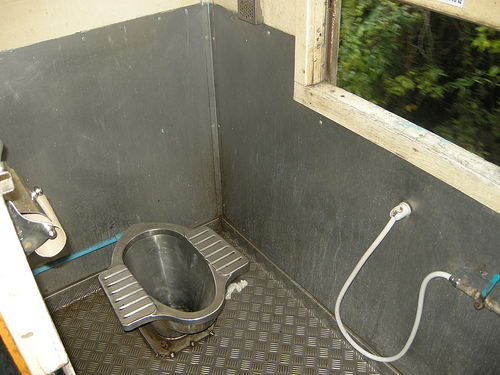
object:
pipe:
[22, 187, 67, 259]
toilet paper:
[23, 195, 67, 257]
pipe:
[32, 231, 125, 279]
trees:
[341, 12, 486, 130]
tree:
[331, 0, 499, 166]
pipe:
[447, 267, 500, 318]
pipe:
[474, 273, 499, 310]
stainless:
[225, 322, 307, 367]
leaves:
[333, 0, 499, 173]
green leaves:
[337, 0, 499, 166]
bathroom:
[0, 0, 498, 372]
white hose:
[333, 202, 453, 365]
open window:
[308, 0, 500, 180]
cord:
[334, 200, 453, 362]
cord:
[390, 201, 412, 220]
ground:
[423, 147, 447, 194]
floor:
[41, 215, 403, 374]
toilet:
[97, 221, 248, 358]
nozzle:
[389, 202, 411, 221]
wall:
[0, 0, 499, 375]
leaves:
[386, 74, 409, 94]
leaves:
[351, 30, 379, 53]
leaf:
[351, 25, 365, 37]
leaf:
[391, 70, 415, 91]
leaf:
[385, 83, 406, 98]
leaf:
[426, 85, 442, 97]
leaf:
[467, 74, 494, 89]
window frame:
[294, 0, 498, 219]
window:
[294, 0, 500, 211]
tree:
[359, 22, 479, 130]